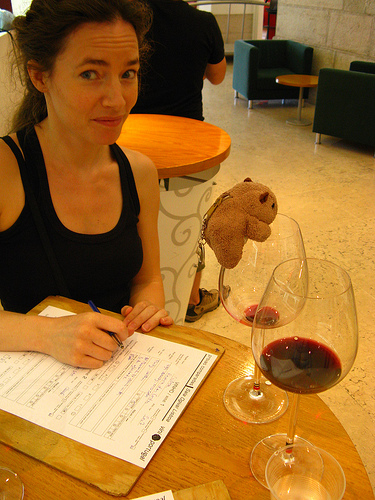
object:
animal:
[202, 176, 277, 269]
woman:
[0, 0, 175, 371]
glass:
[217, 212, 308, 424]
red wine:
[243, 304, 280, 326]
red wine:
[259, 335, 342, 396]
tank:
[0, 118, 146, 315]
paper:
[140, 345, 180, 392]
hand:
[49, 309, 129, 370]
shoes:
[185, 288, 221, 323]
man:
[130, 0, 226, 122]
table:
[116, 113, 231, 181]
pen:
[87, 299, 127, 351]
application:
[0, 304, 219, 469]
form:
[0, 303, 218, 469]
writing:
[0, 305, 220, 470]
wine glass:
[249, 256, 360, 493]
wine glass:
[218, 212, 307, 424]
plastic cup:
[263, 439, 345, 500]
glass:
[251, 257, 358, 491]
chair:
[232, 37, 313, 109]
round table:
[0, 292, 375, 500]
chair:
[312, 59, 374, 151]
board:
[0, 295, 226, 495]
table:
[276, 74, 318, 127]